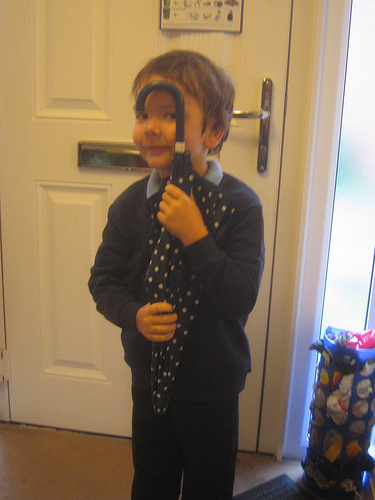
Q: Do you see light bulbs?
A: No, there are no light bulbs.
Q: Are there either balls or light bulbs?
A: No, there are no light bulbs or balls.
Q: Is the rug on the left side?
A: No, the rug is on the right of the image.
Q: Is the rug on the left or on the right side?
A: The rug is on the right of the image.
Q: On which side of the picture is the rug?
A: The rug is on the right of the image.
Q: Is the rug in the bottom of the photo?
A: Yes, the rug is in the bottom of the image.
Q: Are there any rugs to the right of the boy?
A: Yes, there is a rug to the right of the boy.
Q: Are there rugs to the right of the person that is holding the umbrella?
A: Yes, there is a rug to the right of the boy.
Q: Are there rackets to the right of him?
A: No, there is a rug to the right of the boy.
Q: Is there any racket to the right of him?
A: No, there is a rug to the right of the boy.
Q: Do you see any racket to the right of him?
A: No, there is a rug to the right of the boy.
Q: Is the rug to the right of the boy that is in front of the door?
A: Yes, the rug is to the right of the boy.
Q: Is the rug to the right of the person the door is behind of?
A: Yes, the rug is to the right of the boy.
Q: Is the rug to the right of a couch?
A: No, the rug is to the right of the boy.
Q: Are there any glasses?
A: No, there are no glasses.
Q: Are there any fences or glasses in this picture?
A: No, there are no glasses or fences.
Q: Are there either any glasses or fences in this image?
A: No, there are no glasses or fences.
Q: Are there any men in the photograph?
A: No, there are no men.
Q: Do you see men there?
A: No, there are no men.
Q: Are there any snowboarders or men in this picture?
A: No, there are no men or snowboarders.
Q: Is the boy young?
A: Yes, the boy is young.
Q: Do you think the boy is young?
A: Yes, the boy is young.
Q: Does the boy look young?
A: Yes, the boy is young.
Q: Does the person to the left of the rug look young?
A: Yes, the boy is young.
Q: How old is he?
A: The boy is young.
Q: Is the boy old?
A: No, the boy is young.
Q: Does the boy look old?
A: No, the boy is young.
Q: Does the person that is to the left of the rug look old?
A: No, the boy is young.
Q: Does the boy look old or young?
A: The boy is young.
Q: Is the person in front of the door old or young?
A: The boy is young.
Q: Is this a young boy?
A: Yes, this is a young boy.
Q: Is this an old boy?
A: No, this is a young boy.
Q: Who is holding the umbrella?
A: The boy is holding the umbrella.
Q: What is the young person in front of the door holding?
A: The boy is holding the umbrella.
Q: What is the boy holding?
A: The boy is holding the umbrella.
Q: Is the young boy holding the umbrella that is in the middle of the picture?
A: Yes, the boy is holding the umbrella.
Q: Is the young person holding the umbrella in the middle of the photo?
A: Yes, the boy is holding the umbrella.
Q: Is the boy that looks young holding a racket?
A: No, the boy is holding the umbrella.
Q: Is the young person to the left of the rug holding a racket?
A: No, the boy is holding the umbrella.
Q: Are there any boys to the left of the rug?
A: Yes, there is a boy to the left of the rug.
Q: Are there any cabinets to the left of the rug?
A: No, there is a boy to the left of the rug.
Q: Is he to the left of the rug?
A: Yes, the boy is to the left of the rug.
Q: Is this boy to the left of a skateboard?
A: No, the boy is to the left of the rug.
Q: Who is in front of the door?
A: The boy is in front of the door.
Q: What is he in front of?
A: The boy is in front of the door.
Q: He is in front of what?
A: The boy is in front of the door.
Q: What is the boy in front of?
A: The boy is in front of the door.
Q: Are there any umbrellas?
A: Yes, there is an umbrella.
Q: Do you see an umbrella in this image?
A: Yes, there is an umbrella.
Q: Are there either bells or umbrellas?
A: Yes, there is an umbrella.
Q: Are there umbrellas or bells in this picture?
A: Yes, there is an umbrella.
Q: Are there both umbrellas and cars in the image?
A: No, there is an umbrella but no cars.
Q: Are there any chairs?
A: No, there are no chairs.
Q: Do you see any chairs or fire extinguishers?
A: No, there are no chairs or fire extinguishers.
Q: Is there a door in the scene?
A: Yes, there is a door.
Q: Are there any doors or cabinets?
A: Yes, there is a door.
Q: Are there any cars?
A: No, there are no cars.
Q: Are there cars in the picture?
A: No, there are no cars.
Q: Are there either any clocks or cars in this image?
A: No, there are no cars or clocks.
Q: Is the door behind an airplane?
A: No, the door is behind a boy.